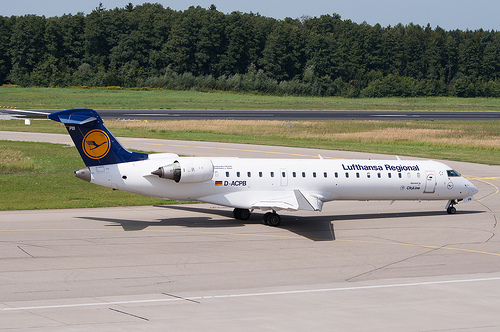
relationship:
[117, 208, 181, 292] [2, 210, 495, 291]
section of runway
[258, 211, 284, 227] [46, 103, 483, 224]
gear of aeroplane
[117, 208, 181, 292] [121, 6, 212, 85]
section of forest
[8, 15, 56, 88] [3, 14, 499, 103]
portion of plantation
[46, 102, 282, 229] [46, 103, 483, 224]
back of aeroplane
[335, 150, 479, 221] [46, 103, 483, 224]
front of aeroplane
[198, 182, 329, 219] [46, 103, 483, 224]
wing of aeroplane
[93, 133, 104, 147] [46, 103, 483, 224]
yellow of aeroplane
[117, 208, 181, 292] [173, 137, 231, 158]
section of road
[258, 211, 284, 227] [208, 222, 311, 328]
gear on ground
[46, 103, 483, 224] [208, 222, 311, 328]
aeroplane on ground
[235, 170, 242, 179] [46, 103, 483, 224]
window on aeroplane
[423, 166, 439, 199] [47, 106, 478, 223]
door on aeroplane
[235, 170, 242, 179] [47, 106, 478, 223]
window on aeroplane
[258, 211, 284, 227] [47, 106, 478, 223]
gear of aeroplane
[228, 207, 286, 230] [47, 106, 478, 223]
gear on aeroplane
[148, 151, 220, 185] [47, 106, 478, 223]
engine on aeroplane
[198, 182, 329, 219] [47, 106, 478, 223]
wing on aeroplane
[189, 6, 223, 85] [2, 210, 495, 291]
forest behind runway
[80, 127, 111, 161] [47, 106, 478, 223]
logo on aeroplane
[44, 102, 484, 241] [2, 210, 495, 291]
plane on runway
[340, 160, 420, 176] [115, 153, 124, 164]
name in blue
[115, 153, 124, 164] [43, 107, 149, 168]
blue on tail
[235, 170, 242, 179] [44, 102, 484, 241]
window on plane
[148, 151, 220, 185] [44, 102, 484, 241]
engine on plane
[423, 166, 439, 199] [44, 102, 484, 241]
door on plane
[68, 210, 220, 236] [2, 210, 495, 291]
shadow on runway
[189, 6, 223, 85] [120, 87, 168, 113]
forest on grass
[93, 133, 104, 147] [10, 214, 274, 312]
yellow on tarmac